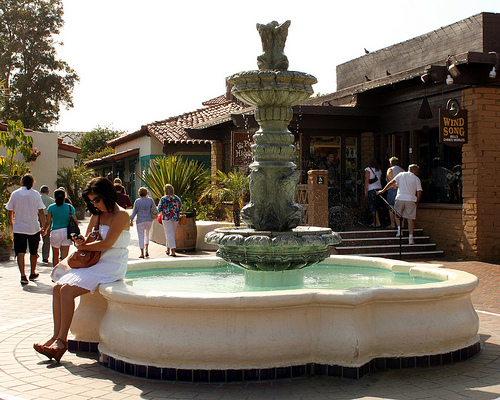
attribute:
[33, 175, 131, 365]
woman — on vacation, tan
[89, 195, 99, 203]
sunglasses — dark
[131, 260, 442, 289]
water — green, bluish green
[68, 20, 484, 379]
fountain — white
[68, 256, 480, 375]
basin — white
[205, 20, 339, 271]
fountain — green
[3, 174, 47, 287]
man — walking, enjoying day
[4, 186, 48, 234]
shirt — white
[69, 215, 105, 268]
purse — brown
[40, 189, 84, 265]
woman — walking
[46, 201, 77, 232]
shirt — green, turquoise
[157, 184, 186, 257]
woman — walking, shopping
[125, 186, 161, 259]
woman — walking, shopping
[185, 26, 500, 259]
building — restaurant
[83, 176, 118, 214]
hair — dark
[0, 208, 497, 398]
plaza — stone, beige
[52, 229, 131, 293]
dress — white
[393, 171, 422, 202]
shirt — white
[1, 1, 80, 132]
tree — distant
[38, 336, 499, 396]
shadow — dark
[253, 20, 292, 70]
statue — ornate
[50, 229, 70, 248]
shorts — white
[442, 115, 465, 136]
letters — gold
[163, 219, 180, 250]
pants — white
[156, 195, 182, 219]
shirt — multi-colored